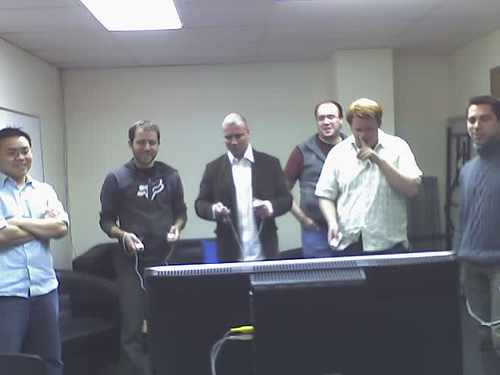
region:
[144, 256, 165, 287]
Corner of a black tv on the floor.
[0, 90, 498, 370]
A group of men in the foreground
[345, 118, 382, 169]
Man's hand is on his mouth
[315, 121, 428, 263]
Man is wearing a button up shirt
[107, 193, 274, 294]
Two men holding controllers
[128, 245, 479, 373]
The back of a TV Screen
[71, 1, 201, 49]
A light on the ceiling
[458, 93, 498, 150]
Man has dark colored hair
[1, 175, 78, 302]
Man has his arms crossed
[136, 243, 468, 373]
The back of a TV screen is black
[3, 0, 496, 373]
Photo was taken indoors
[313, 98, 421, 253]
blond man touching his nose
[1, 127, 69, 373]
man in blue wearing glasses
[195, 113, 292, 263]
man in black vest holding a video game control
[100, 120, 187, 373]
man in black hoodie playing a video game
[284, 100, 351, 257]
man standing in the back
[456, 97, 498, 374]
man wearing a blue sweater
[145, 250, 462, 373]
tv in front of the guys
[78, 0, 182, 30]
light in the ceiling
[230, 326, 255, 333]
yellow plug connected to TV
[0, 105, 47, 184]
whiteboard on the side of the room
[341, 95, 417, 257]
man wearing white shirt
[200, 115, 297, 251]
man wearnig black jacket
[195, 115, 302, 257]
man wearing white shirt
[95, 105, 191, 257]
man wearing black shirt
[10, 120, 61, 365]
man wearing blue shirt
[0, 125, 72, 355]
man wearing blue pants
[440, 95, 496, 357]
man wearing blue sweater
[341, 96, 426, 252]
man playing video game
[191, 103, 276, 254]
man holding video controller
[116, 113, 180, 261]
man holding video controller